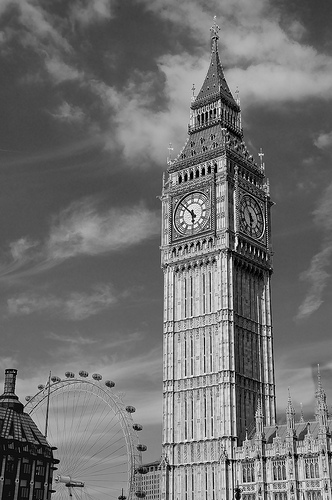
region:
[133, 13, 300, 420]
a big tower on a building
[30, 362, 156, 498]
a carnival behind a building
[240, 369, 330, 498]
building on the right side of tower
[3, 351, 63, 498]
an old building in front or tower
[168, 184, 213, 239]
clock in front of a tower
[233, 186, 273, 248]
clock on side of a tower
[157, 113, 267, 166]
tower has decoration structures on the roof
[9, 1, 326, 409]
a cloudy sky behind a tower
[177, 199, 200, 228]
hands of tower are black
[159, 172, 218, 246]
clock is in a square frame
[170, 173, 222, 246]
Clock on tall building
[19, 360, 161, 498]
Ferris wheel in front of building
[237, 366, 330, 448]
three smaller steeples on building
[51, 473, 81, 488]
White center piece of ferris wheel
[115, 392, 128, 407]
Car missing from ferris wheel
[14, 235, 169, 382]
Wispy clouds in the sky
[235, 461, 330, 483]
Three sets of three arched windows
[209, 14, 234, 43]
Cross on top of tall steeple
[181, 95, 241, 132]
Balcony on top of steeple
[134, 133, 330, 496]
Large old fashioned building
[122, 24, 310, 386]
Black and white image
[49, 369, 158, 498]
Large Ferris wheel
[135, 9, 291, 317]
Big Ben in London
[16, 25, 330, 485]
London cityscape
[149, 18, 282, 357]
A clock tower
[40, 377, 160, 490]
The London Eye Ferris wheel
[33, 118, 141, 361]
Sky with clouds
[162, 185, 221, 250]
Clock tower at 5:53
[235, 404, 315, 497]
Palace of Westminister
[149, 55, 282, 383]
The Elizabeth clock tower, also nicknamed Big Ben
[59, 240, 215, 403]
the sky is grey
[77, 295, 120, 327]
the sky is grey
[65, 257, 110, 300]
the sky is grey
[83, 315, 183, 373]
the sky is grey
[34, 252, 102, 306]
the sky is grey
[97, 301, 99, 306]
the sky is grey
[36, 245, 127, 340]
the sky is grey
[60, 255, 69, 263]
the sky is grey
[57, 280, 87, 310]
the sky is grey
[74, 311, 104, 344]
the sky is grey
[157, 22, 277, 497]
Large tower with a clock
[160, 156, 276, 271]
Section of the tower with the clock on each side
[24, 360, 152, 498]
Ferris wheel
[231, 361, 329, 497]
Several buildings lying aside the tower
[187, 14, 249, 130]
Top piece of the power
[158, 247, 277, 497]
Foundation of the tower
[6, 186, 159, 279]
Small cloud in the sky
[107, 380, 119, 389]
Seat on the Ferris wheel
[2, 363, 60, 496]
Building that's separated from the tower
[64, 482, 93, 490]
Center piece of the tower